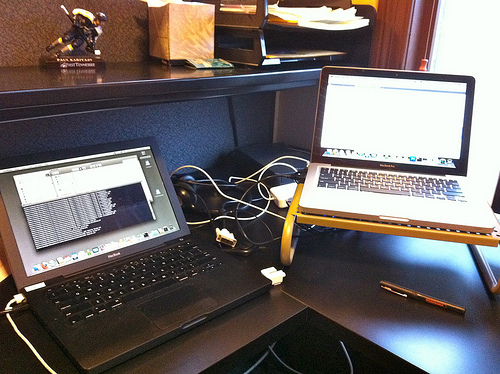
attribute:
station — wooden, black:
[0, 57, 499, 373]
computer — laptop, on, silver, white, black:
[293, 61, 497, 237]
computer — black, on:
[1, 132, 276, 373]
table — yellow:
[269, 167, 500, 302]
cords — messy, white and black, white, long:
[168, 150, 345, 257]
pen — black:
[376, 276, 469, 319]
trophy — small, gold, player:
[38, 1, 111, 78]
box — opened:
[144, 1, 217, 71]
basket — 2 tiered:
[195, 0, 359, 70]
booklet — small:
[182, 53, 236, 76]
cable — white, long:
[166, 149, 321, 248]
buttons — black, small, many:
[315, 165, 470, 209]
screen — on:
[318, 72, 468, 174]